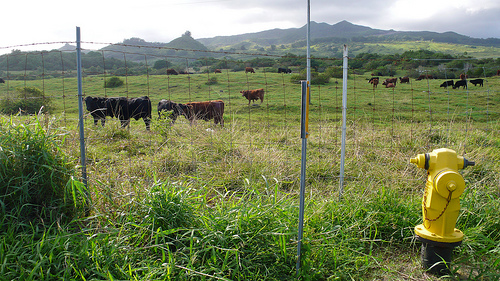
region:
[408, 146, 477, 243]
a yellow fire hydrant by a field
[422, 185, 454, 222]
a chain on a yellow hydrant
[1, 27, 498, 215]
a fence by a field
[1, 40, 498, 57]
a barbed wire along a fence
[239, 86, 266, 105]
a brown cow standing alone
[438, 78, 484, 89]
a group of black cows grazing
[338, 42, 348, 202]
a white pole on the fence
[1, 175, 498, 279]
tall grass along a fence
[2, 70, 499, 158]
a field with cows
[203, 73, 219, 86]
a patch of tall grass in a field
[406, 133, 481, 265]
yellow fire hydrant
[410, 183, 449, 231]
brown chain on a fire hydrant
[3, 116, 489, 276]
green bushes outside of the metal fence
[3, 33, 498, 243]
a metal fence in the pasture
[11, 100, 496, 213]
patch of dead grass and vegetation in the pasture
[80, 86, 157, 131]
two black cows standing together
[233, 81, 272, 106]
one brown cow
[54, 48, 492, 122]
group of cows grazing in the field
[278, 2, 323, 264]
metal pole in the ground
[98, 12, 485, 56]
mountain range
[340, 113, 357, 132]
part of a fence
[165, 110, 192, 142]
edge of a fence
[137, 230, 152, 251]
part of the grass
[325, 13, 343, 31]
part of a landscape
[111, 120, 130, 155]
edge of a fence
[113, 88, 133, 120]
body of a cow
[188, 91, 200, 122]
side of a cow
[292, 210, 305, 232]
edge of a pole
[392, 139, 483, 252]
yellow hydrant in the grass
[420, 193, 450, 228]
chain hanging off of the hydrant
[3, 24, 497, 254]
fence around a cow pasture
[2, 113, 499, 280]
tall green grass around the fence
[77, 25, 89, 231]
metal fence poles in the ground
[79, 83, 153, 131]
two black cows standing in the field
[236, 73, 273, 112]
a brown cow standing in the field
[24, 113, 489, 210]
dead yellow grass on the ground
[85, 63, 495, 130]
cows grazing in a field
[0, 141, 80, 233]
yellow fire hydrant by field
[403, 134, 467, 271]
yellow fire hydrant with black chains by field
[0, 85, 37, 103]
cow standing in field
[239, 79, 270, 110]
cow standing in field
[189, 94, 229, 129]
cow standing in field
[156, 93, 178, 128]
cow standing in field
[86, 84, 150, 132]
cow standing in field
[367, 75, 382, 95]
cow standing in field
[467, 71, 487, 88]
cow standing in field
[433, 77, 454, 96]
cow standing in field